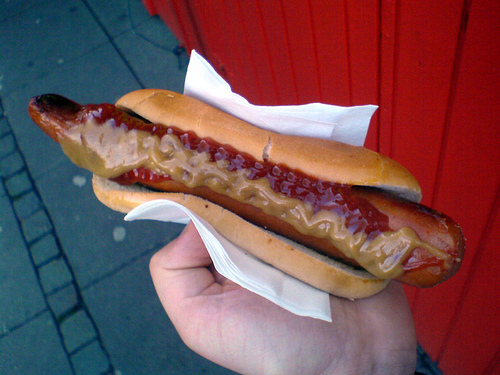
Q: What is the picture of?
A: A hotdog.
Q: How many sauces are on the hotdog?
A: 2.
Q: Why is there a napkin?
A: It is messy.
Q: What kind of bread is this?
A: Hot dog roll.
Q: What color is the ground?
A: Green.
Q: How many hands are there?
A: 1.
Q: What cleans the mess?
A: A napkin.